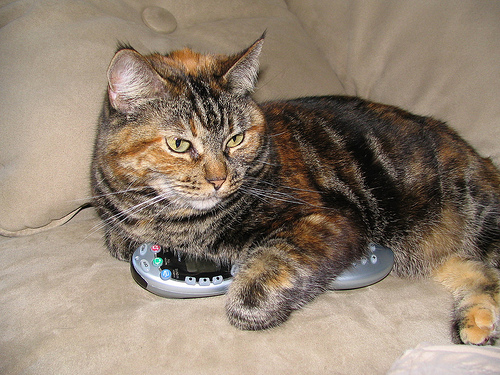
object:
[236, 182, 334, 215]
whiskers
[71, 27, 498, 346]
cat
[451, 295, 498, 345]
paw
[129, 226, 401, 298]
remote control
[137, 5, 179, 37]
button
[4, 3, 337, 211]
pillow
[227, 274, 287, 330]
paw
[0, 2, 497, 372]
couch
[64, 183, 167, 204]
whiskers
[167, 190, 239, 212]
mouth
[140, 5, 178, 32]
button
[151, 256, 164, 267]
button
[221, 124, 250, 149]
eyes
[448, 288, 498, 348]
paw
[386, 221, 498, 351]
leg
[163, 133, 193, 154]
eye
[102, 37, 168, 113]
ear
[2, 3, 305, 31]
pillow